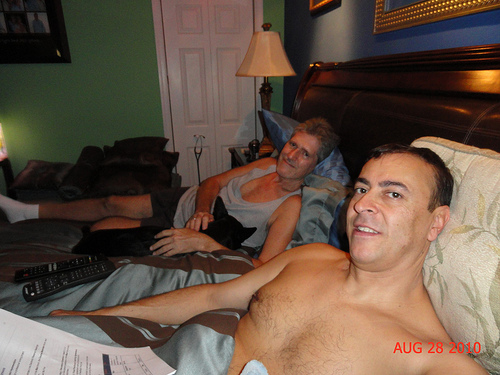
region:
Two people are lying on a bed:
[0, 40, 497, 372]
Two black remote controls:
[5, 245, 117, 305]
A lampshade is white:
[226, 25, 301, 80]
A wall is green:
[0, 0, 285, 176]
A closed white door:
[146, 0, 266, 191]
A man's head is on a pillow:
[337, 127, 497, 368]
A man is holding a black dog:
[65, 110, 345, 265]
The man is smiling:
[336, 135, 456, 270]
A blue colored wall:
[280, 0, 495, 116]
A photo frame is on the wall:
[0, 0, 76, 71]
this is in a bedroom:
[29, 21, 411, 308]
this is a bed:
[68, 248, 237, 359]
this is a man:
[310, 130, 483, 365]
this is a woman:
[147, 117, 337, 224]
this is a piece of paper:
[5, 325, 189, 371]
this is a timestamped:
[378, 340, 493, 373]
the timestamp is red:
[378, 325, 498, 370]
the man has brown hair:
[328, 115, 471, 207]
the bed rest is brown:
[356, 32, 484, 121]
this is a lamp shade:
[252, 30, 374, 156]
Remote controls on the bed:
[5, 250, 133, 303]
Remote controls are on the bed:
[10, 251, 122, 307]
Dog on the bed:
[65, 201, 260, 263]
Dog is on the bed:
[68, 192, 262, 265]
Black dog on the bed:
[72, 192, 260, 259]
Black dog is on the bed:
[67, 192, 262, 262]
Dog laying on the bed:
[72, 197, 259, 256]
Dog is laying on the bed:
[71, 195, 260, 258]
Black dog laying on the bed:
[67, 192, 262, 261]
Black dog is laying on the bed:
[60, 193, 264, 263]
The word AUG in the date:
[395, 335, 422, 357]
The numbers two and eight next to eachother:
[427, 335, 442, 360]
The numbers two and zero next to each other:
[449, 341, 466, 356]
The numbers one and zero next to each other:
[466, 339, 483, 357]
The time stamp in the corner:
[387, 336, 489, 361]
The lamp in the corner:
[236, 25, 293, 129]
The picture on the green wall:
[3, 5, 80, 66]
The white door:
[160, 8, 254, 178]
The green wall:
[17, 0, 274, 235]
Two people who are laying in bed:
[39, 116, 450, 371]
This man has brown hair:
[391, 143, 415, 192]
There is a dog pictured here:
[122, 225, 244, 320]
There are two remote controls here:
[31, 260, 90, 281]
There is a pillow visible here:
[458, 232, 475, 312]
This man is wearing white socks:
[0, 185, 30, 262]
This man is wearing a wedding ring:
[190, 212, 197, 226]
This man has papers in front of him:
[62, 355, 70, 365]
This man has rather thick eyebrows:
[381, 175, 393, 205]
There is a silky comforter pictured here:
[173, 327, 183, 361]